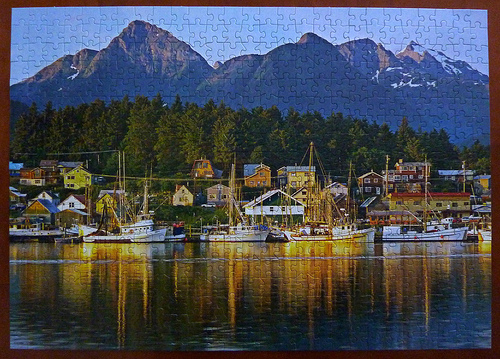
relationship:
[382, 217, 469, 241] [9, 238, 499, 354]
boat in water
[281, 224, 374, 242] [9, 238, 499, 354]
boat in water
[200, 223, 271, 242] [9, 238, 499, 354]
boat in water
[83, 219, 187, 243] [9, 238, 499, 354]
boat in water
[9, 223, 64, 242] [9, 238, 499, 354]
boat in water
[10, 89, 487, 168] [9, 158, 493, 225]
trees behind homes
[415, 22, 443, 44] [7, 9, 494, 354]
piece in puzzle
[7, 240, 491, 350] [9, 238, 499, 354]
reflection in water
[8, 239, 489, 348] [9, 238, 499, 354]
lights reflecting in water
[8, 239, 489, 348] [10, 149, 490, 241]
lights from boats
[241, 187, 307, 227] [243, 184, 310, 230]
trim on boathouse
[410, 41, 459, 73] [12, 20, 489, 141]
snow covering mountain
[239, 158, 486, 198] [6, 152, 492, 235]
houses on hill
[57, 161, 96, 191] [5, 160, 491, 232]
building on hill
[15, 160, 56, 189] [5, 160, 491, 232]
building on hill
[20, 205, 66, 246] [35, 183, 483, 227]
boat on pier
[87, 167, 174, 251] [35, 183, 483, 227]
boat on pier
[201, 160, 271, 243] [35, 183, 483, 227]
boat on pier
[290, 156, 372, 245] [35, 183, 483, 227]
boat on pier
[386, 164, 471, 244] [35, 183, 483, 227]
boat on pier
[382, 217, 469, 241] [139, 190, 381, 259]
boat on shore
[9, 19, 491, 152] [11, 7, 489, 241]
mountains in background